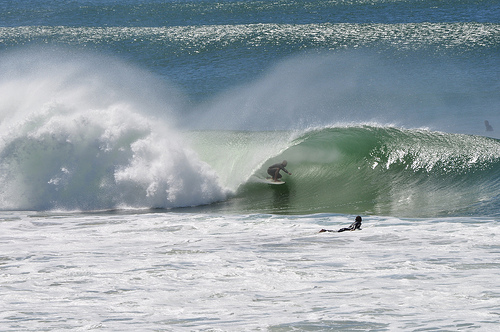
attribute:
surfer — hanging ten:
[229, 123, 316, 223]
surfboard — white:
[270, 179, 285, 185]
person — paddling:
[323, 217, 372, 229]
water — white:
[0, 206, 500, 330]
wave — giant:
[23, 100, 458, 221]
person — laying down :
[315, 206, 367, 235]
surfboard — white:
[264, 176, 287, 186]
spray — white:
[38, 37, 175, 130]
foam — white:
[0, 213, 498, 329]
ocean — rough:
[1, 1, 497, 330]